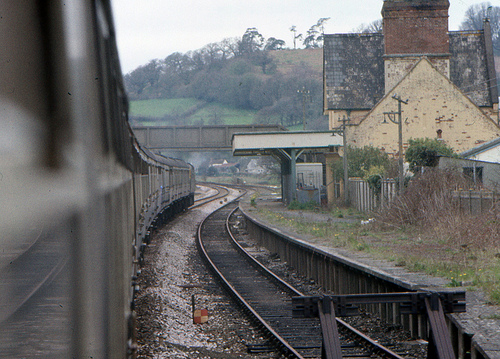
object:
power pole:
[392, 92, 407, 194]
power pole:
[336, 113, 348, 203]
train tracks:
[193, 183, 407, 359]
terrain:
[133, 93, 273, 165]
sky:
[108, 1, 498, 79]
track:
[188, 180, 405, 359]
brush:
[370, 163, 497, 265]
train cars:
[0, 2, 195, 357]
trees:
[123, 16, 363, 131]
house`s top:
[357, 55, 498, 127]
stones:
[123, 223, 196, 356]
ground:
[121, 95, 498, 357]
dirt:
[345, 252, 367, 260]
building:
[332, 14, 467, 190]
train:
[2, 0, 195, 359]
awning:
[230, 131, 345, 155]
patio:
[235, 131, 340, 203]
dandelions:
[250, 198, 324, 238]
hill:
[131, 49, 323, 124]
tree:
[402, 132, 448, 172]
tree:
[348, 143, 393, 190]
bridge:
[133, 124, 290, 152]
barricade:
[291, 289, 465, 359]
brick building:
[317, 0, 499, 217]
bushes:
[390, 175, 485, 237]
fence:
[412, 179, 498, 219]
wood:
[212, 263, 257, 273]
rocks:
[132, 243, 208, 340]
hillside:
[124, 12, 388, 180]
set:
[61, 179, 384, 349]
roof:
[319, 31, 384, 112]